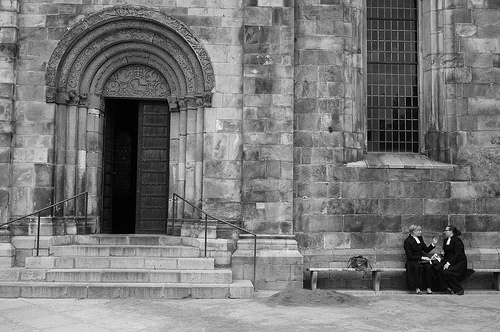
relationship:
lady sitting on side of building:
[434, 225, 476, 295] [17, 10, 498, 212]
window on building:
[362, 0, 425, 160] [0, 0, 499, 294]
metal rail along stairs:
[167, 190, 258, 283] [1, 230, 250, 299]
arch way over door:
[43, 4, 217, 113] [96, 91, 173, 232]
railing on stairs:
[165, 189, 265, 291] [0, 232, 253, 299]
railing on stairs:
[3, 187, 84, 263] [0, 232, 253, 299]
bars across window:
[365, 0, 425, 160] [367, 4, 423, 154]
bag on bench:
[346, 255, 372, 272] [306, 263, 499, 293]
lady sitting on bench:
[434, 225, 476, 295] [306, 262, 498, 291]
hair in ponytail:
[446, 223, 466, 240] [455, 225, 464, 237]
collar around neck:
[411, 235, 428, 242] [407, 232, 418, 239]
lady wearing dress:
[403, 224, 440, 294] [408, 240, 425, 282]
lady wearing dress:
[434, 225, 476, 295] [446, 241, 462, 287]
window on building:
[362, 0, 425, 154] [0, 4, 498, 329]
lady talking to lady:
[400, 222, 429, 296] [435, 223, 470, 293]